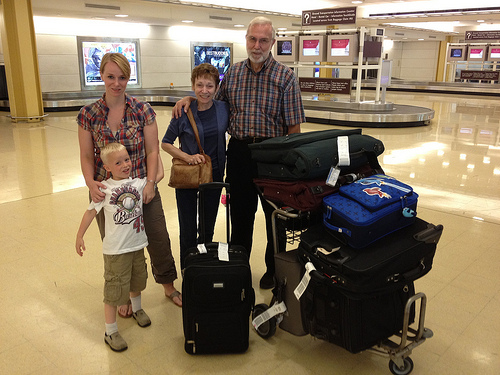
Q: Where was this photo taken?
A: At the airport.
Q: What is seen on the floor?
A: Reflection of lights.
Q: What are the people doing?
A: Posing for picture?.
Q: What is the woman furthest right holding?
A: A purse.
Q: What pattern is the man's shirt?
A: Plaid.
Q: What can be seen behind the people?
A: A luggage carousel.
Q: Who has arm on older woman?
A: Man in a plaid shirt.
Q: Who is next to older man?
A: Woman in blue outfit.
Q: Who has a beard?
A: The older man.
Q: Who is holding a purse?
A: The older woman.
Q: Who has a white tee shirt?
A: The boy.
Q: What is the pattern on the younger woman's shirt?
A: Plaid.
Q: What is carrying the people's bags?
A: A luggage cart.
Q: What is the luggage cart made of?
A: Metal.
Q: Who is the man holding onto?
A: The older woman.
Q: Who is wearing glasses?
A: The older man.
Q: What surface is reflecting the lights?
A: The floor.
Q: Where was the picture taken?
A: In an airport.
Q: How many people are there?
A: Four.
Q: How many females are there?
A: Two.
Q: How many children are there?
A: One.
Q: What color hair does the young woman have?
A: Blonde.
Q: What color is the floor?
A: Beige.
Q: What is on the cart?
A: Luggage.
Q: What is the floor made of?
A: Tile.